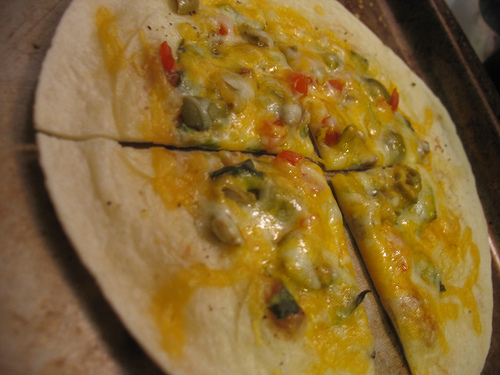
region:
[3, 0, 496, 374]
a pizza with yellow sauce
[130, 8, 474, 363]
yellow melted cheese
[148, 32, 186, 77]
red pepper on pizza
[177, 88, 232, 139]
meat ball of pizza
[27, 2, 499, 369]
pizza cut in four pieces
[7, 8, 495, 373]
pizza on a brown table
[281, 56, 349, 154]
pieces of red paper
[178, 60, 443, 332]
ball meat on tortilla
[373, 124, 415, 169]
a ball meat under melted cheese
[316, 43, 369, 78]
some diced green vegetables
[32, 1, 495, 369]
quesadilla is round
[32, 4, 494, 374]
quesadilla is cut into four pieces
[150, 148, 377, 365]
melted orange and white cheese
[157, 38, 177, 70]
chopped red tomato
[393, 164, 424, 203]
green jalapeno slice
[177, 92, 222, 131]
mushroom piece with melted cheese on top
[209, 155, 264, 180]
piece of cilantro in melted cheese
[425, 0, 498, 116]
edge of silver pan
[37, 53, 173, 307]
white flour tortilla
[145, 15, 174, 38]
dark spots on flour tortilla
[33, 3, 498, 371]
white bread food profuct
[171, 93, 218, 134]
green vegetable on top of baked food item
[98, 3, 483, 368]
yellow glaze on top of baked food item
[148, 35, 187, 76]
red pepper bits on top of baked food item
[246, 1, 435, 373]
vertical slice in food product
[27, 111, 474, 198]
horizontal slice in cooked food item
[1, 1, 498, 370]
metal pan beneath baked food item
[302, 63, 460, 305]
vegetables melted into yellow sauce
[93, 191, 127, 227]
brown fleck on white breaded part of food item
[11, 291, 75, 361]
brown burn marks on metal pan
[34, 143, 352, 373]
A piece of a pizza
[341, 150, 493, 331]
A piece of a pizza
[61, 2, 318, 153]
A piece of a pizza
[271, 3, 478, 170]
A piece of a pizza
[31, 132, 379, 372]
a half slice of a quesadilla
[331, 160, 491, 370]
a half slice of a quesadilla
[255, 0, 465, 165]
a half slice of a quesadilla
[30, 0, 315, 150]
a half slice of a quesadilla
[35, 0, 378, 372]
a quesadilla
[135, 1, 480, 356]
some melted cheese on a quesadilla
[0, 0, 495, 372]
A flat top grill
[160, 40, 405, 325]
some chopped tomatoes on a quesadilla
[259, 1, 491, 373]
A quesadilla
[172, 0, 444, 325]
some chopped peppers on a quesadilla